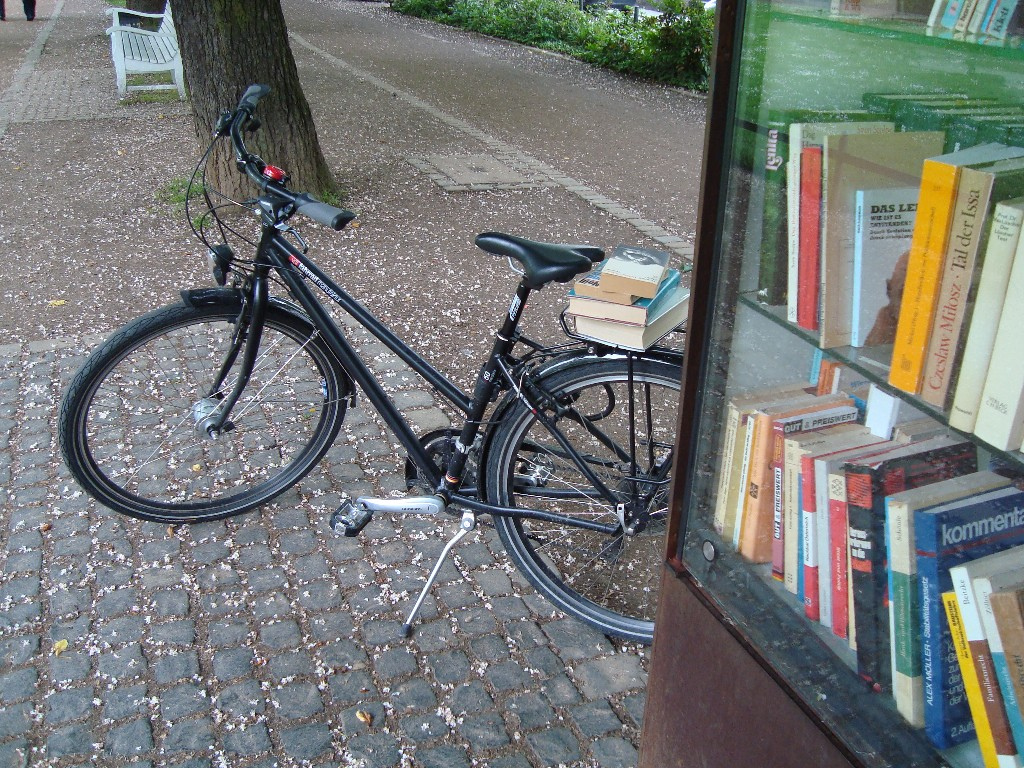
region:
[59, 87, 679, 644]
a parked bicycle on its stand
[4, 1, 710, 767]
a paved sidewalk dotted with leaves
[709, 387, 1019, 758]
a row of books on a shelf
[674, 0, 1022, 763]
a selection of books behind a window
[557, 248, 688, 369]
a stack of books sitting on a rack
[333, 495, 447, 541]
a black and silver bicycle pedal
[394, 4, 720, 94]
a green hedge bordering the sidewalk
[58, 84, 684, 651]
a bicycle with a red light on its handlebar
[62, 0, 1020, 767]
a bicycle next to a book stand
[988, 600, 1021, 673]
book on the shelf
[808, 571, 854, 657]
book on the shelf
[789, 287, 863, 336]
book on the shelf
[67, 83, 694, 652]
Black commuter bicycle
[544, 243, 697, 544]
Luggage rack on back of commuter bike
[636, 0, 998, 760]
Glass encased book shelf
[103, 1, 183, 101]
White park bench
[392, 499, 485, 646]
Kickstand with rubber tip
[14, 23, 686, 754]
Stone pathway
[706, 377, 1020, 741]
Book titles in German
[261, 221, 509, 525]
Bike has girl's frame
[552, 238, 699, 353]
Four books strapped to bike's luggage rack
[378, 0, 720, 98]
Bushes beside stone pathway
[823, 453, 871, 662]
books in a window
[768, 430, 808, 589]
books in a window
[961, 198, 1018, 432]
books in a window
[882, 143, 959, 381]
books in a window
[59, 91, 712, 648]
Bike near a tree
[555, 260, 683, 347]
Books on the bike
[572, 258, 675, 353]
Books on top of bicycle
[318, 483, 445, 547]
Pedal on the bike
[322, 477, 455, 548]
Pedal on the bicycle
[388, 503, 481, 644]
Kickstand on the bike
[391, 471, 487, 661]
Kickstand on the bicycle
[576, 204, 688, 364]
books on the back of bike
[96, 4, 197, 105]
white bench between the trees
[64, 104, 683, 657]
bicycle is black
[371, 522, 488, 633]
bike is resting on the kickstand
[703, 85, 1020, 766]
books on the shelves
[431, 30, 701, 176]
sidewalk on the side of the median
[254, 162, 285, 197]
red bell on the handle bar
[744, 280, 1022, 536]
shelf is made of glass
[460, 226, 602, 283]
black seat on the bicycle